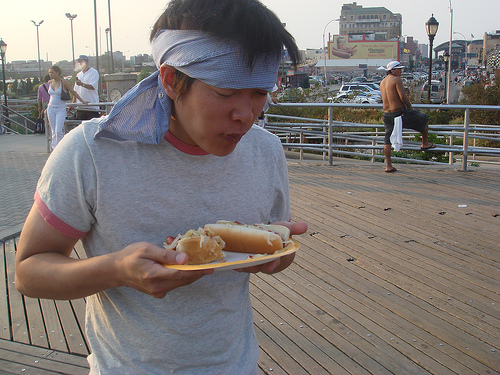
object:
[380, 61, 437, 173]
man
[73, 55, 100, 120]
man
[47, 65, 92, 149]
woman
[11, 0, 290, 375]
man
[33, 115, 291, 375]
shirt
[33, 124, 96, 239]
sleeve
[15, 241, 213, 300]
arm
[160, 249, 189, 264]
thumb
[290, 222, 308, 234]
thumb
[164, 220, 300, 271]
food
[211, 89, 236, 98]
eye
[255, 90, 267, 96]
eye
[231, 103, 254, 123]
nose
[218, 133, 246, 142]
lip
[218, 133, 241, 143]
lip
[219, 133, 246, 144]
mouth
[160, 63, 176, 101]
ear